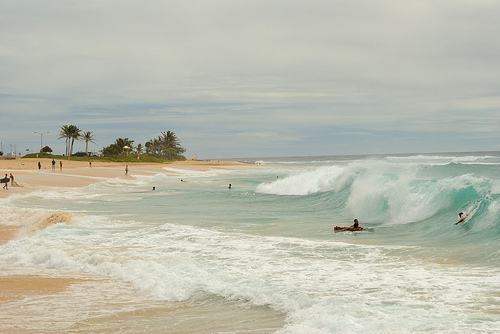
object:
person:
[457, 211, 463, 219]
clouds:
[1, 2, 498, 148]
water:
[143, 191, 234, 213]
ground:
[310, 187, 325, 202]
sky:
[12, 19, 263, 148]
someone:
[350, 218, 360, 231]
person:
[2, 173, 9, 190]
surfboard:
[0, 177, 11, 183]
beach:
[0, 153, 497, 332]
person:
[88, 158, 93, 167]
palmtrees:
[79, 131, 97, 152]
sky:
[257, 62, 399, 143]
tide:
[114, 222, 388, 309]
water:
[284, 151, 474, 248]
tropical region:
[0, 1, 498, 331]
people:
[180, 178, 187, 183]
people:
[228, 183, 232, 189]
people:
[50, 158, 57, 171]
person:
[59, 160, 64, 171]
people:
[152, 185, 156, 189]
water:
[163, 241, 261, 330]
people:
[37, 161, 42, 170]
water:
[0, 261, 149, 331]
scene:
[0, 0, 499, 333]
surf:
[255, 165, 357, 195]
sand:
[0, 157, 177, 330]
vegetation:
[144, 129, 186, 162]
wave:
[346, 154, 499, 235]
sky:
[355, 102, 494, 150]